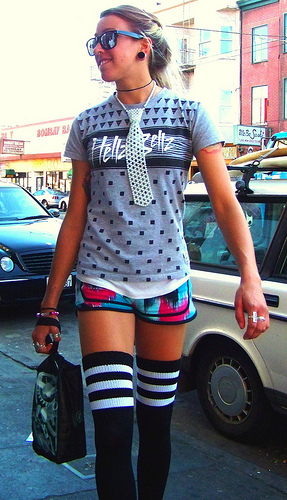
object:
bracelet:
[38, 311, 61, 314]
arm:
[38, 125, 89, 309]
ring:
[246, 313, 257, 325]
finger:
[243, 311, 258, 338]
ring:
[38, 344, 46, 349]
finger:
[39, 339, 56, 353]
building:
[241, 0, 286, 146]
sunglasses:
[88, 32, 147, 56]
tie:
[114, 81, 156, 208]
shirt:
[64, 89, 224, 284]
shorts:
[75, 278, 199, 325]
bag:
[31, 314, 86, 463]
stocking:
[83, 351, 138, 499]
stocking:
[136, 355, 184, 498]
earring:
[135, 52, 147, 60]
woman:
[31, 4, 273, 496]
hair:
[99, 5, 181, 90]